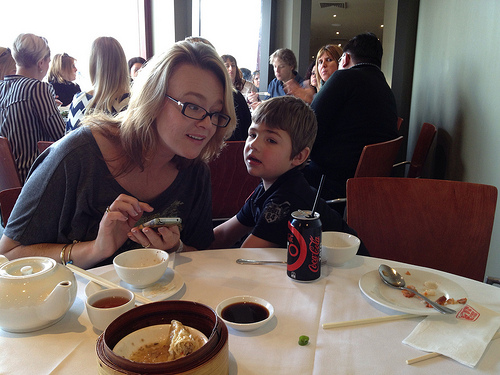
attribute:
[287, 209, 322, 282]
can — black, red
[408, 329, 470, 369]
napkin — white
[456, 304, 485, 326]
writing — red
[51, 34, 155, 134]
woman — blonde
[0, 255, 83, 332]
teapot — white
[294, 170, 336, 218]
straw — black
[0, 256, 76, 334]
tea kettle — white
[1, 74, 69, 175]
shirt — black, white, striped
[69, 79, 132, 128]
shirt — blue, white